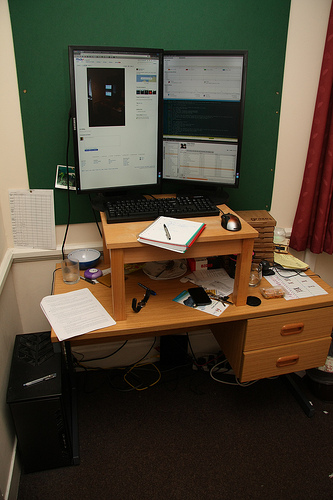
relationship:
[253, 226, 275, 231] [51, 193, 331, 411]
box on desk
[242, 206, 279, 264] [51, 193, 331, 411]
box on desk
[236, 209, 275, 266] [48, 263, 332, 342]
box on desk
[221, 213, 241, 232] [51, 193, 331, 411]
mouse on desk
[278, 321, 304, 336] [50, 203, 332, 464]
drawer pull on desk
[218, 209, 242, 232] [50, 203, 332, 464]
mouse on desk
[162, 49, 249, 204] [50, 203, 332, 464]
monitor on desk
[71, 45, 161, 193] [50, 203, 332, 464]
monitor on desk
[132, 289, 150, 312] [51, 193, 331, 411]
black watch on desk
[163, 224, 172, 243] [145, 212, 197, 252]
pen on notebook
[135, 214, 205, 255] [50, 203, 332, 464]
notebook on desk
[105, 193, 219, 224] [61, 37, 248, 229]
keyboard for computer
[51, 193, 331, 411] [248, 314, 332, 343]
desk on drawer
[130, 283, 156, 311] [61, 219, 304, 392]
black watch on desk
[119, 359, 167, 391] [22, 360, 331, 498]
cord on ground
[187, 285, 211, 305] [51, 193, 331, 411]
cellphone on desk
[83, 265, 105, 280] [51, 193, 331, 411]
inhaler on desk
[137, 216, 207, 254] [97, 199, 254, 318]
notebook on desk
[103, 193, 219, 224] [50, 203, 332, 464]
keyboard on desk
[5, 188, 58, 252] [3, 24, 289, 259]
paper on wall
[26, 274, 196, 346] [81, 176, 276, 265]
papers on desk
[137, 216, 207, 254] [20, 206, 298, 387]
notebook on desk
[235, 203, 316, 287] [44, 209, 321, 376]
cd rack on desk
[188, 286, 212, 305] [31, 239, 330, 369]
cellphone on desk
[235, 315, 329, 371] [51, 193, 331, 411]
drawer on desk